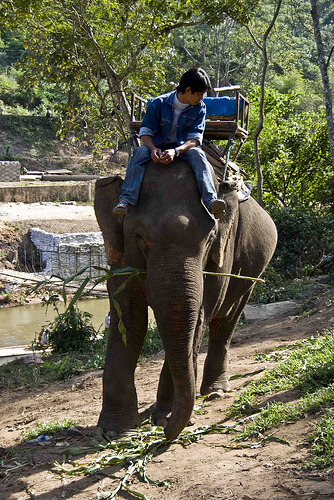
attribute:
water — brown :
[11, 269, 185, 378]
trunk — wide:
[144, 254, 204, 441]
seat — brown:
[128, 94, 251, 139]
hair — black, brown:
[178, 68, 212, 95]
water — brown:
[3, 298, 108, 348]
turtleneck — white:
[172, 92, 191, 115]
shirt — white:
[167, 94, 191, 145]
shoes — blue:
[114, 200, 228, 221]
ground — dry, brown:
[2, 374, 329, 499]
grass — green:
[239, 328, 332, 463]